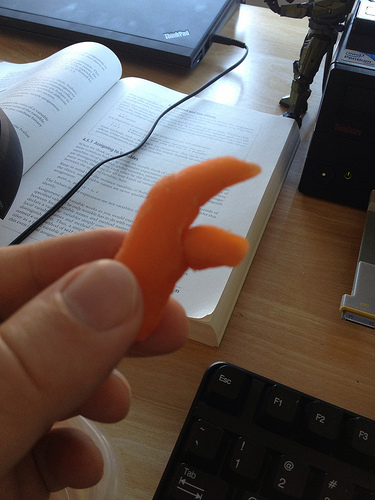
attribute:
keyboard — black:
[148, 360, 369, 499]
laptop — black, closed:
[1, 0, 235, 75]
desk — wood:
[2, 6, 374, 499]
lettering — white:
[176, 373, 373, 499]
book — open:
[2, 40, 299, 349]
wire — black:
[5, 32, 249, 249]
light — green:
[318, 171, 330, 179]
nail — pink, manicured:
[56, 258, 141, 336]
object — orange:
[107, 156, 261, 347]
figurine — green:
[262, 0, 352, 124]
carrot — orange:
[105, 155, 261, 344]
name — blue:
[161, 26, 190, 43]